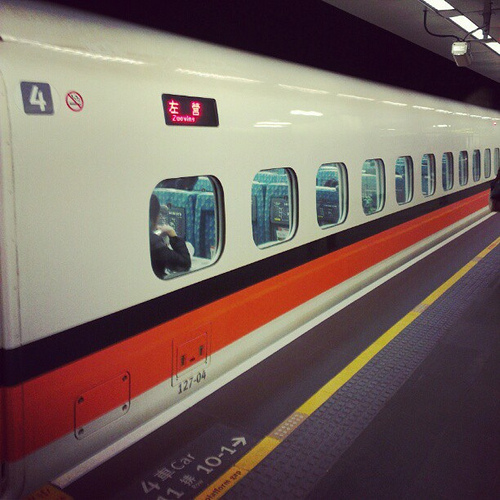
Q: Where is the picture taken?
A: Train station.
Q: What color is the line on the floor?
A: Yellow.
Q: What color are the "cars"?
A: White with red and black stripes.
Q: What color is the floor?
A: Gray.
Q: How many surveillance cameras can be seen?
A: One.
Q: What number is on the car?
A: Four.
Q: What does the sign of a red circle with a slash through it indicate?
A: No smoking.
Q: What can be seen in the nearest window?
A: A person's elbow.